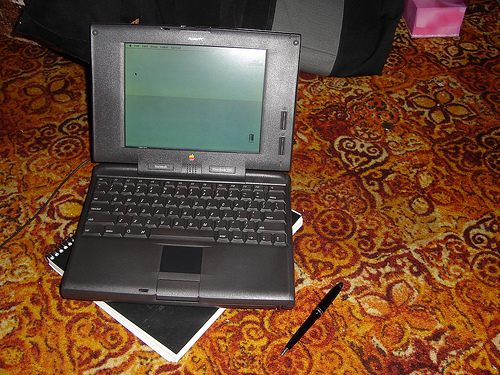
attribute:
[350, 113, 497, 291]
carpet — colorful, orange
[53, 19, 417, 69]
line — grey, thick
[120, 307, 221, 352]
notebook — black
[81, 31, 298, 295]
laptop — silver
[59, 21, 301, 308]
laptop — on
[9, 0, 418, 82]
bag — black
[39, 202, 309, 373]
notebook — black